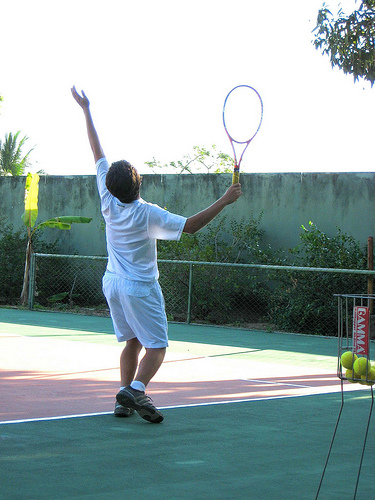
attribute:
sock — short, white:
[128, 380, 146, 391]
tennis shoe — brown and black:
[115, 385, 163, 424]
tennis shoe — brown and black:
[114, 401, 135, 416]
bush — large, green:
[260, 220, 367, 336]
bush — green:
[157, 210, 287, 322]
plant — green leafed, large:
[18, 170, 92, 304]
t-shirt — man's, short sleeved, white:
[92, 157, 185, 279]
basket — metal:
[315, 293, 372, 498]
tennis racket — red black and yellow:
[221, 85, 262, 186]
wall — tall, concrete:
[0, 172, 362, 336]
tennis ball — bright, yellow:
[341, 349, 358, 368]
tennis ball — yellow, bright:
[349, 356, 363, 375]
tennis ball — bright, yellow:
[342, 368, 360, 385]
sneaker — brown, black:
[113, 385, 165, 425]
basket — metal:
[315, 291, 363, 498]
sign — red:
[350, 305, 362, 357]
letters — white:
[355, 309, 363, 351]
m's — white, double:
[352, 323, 363, 343]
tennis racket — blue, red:
[221, 83, 265, 184]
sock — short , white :
[116, 386, 121, 390]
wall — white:
[3, 173, 363, 356]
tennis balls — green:
[339, 347, 355, 457]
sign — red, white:
[352, 308, 363, 357]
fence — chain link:
[32, 244, 357, 359]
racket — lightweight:
[221, 85, 262, 186]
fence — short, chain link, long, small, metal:
[26, 251, 362, 336]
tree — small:
[17, 167, 89, 306]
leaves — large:
[22, 171, 90, 233]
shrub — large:
[255, 219, 362, 334]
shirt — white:
[95, 156, 184, 282]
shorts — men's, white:
[101, 267, 170, 349]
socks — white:
[114, 378, 150, 392]